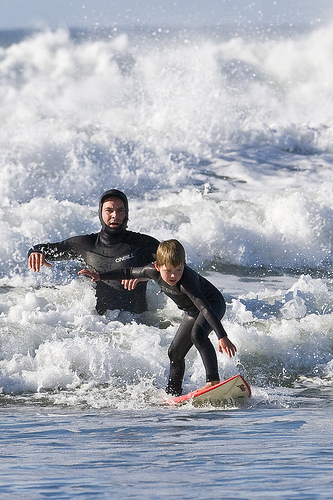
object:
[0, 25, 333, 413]
waves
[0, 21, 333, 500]
ocean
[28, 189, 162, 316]
man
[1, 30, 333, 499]
water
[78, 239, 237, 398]
boy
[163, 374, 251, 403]
board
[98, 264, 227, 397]
wetsuit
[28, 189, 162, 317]
wetsuit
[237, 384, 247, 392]
logo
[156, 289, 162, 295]
zipper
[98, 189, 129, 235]
hood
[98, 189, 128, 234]
head